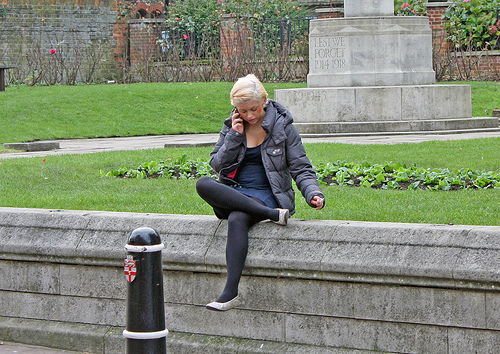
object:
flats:
[203, 293, 248, 311]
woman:
[195, 71, 327, 311]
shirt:
[229, 120, 277, 208]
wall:
[3, 209, 56, 257]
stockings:
[193, 176, 279, 221]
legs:
[203, 209, 249, 312]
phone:
[233, 108, 241, 117]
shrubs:
[8, 15, 196, 80]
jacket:
[199, 100, 326, 212]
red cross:
[123, 260, 135, 280]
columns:
[118, 20, 145, 68]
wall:
[1, 1, 87, 48]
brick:
[112, 23, 119, 27]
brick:
[113, 29, 118, 31]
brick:
[113, 32, 122, 36]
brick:
[117, 37, 122, 40]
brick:
[138, 32, 149, 36]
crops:
[97, 150, 498, 192]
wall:
[393, 85, 437, 120]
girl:
[193, 73, 326, 311]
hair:
[228, 73, 269, 110]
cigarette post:
[121, 225, 167, 352]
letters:
[306, 37, 349, 77]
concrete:
[364, 30, 434, 90]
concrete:
[318, 227, 420, 266]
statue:
[271, 0, 471, 122]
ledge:
[0, 207, 500, 291]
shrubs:
[234, 3, 497, 69]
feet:
[203, 293, 241, 310]